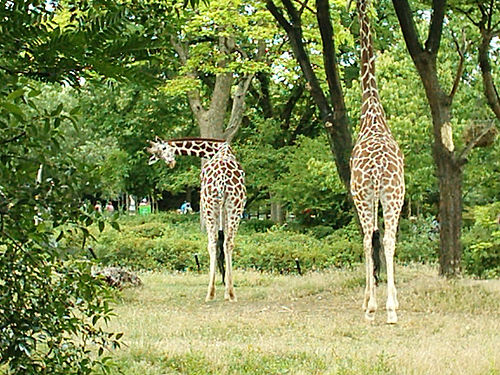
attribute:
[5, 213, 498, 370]
field — grassy, green, yellow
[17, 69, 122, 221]
leaves — green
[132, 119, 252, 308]
giraffe — brown and white.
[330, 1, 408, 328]
giraffe — brown and white.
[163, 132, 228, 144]
mane — brown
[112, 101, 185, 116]
leaves — green 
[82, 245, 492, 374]
grass — brown and green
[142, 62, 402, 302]
giraffes — brown and white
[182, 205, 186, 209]
shirt — blue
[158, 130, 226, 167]
neck — left and back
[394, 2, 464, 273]
trunk — brown